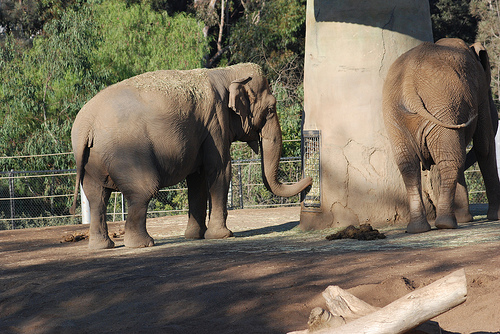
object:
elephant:
[68, 61, 313, 250]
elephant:
[380, 36, 499, 235]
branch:
[286, 268, 468, 333]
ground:
[2, 203, 499, 333]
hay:
[304, 151, 319, 207]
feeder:
[301, 129, 323, 208]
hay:
[126, 63, 269, 105]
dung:
[325, 222, 385, 242]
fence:
[0, 137, 489, 235]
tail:
[401, 93, 481, 130]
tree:
[2, 1, 206, 217]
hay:
[100, 205, 498, 257]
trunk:
[257, 116, 314, 197]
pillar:
[297, 0, 476, 233]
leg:
[107, 165, 159, 248]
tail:
[70, 124, 93, 214]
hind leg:
[80, 167, 116, 250]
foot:
[122, 230, 155, 249]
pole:
[77, 177, 91, 226]